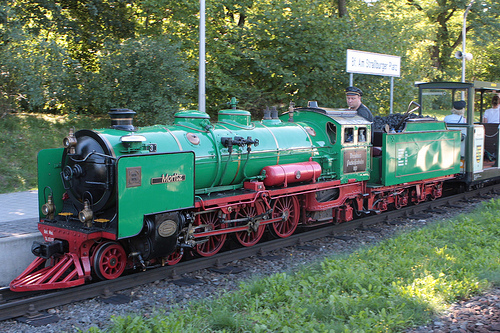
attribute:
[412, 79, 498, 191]
car — windowless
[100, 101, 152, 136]
smoke stacks — small, black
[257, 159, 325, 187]
cylinder — red